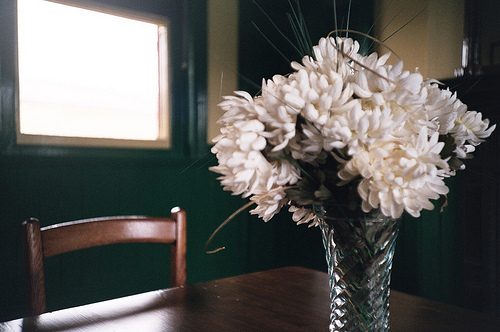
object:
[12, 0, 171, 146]
frame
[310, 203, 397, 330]
vase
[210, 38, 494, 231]
flower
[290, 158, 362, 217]
stems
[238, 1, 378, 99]
corner room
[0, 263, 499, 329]
table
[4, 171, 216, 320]
wall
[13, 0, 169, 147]
window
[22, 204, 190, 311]
chair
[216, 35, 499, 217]
bouquet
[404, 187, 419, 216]
petals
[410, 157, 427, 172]
petals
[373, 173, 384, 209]
petals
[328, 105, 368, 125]
petals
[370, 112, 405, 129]
petals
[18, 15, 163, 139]
daylight